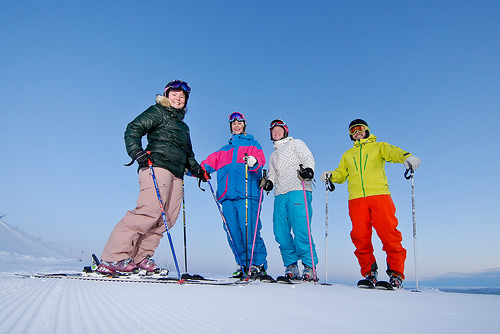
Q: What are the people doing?
A: Skiing.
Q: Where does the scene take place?
A: At a ski slope.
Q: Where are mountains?
A: In the far distance.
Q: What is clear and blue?
A: The sky.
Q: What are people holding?
A: Ski poles.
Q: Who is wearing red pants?
A: Person on far right.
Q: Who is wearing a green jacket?
A: Person on far left.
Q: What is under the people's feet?
A: Skis.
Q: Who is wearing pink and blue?
A: Second person from the left.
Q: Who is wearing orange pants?
A: The skier on the right.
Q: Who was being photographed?
A: A group of skiers.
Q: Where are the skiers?
A: On the snow.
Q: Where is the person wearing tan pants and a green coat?
A: On the left side.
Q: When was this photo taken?
A: During the daytime.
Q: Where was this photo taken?
A: During a ski trip.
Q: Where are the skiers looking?
A: Toward the camera.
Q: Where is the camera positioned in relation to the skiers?
A: Downhill.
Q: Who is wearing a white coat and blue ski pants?
A: The person who is second from the right.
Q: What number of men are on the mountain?
A: 4.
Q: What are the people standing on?
A: Snow.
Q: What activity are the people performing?
A: Skiing.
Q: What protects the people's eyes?
A: Goggles.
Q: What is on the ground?
A: Snow.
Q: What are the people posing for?
A: Picture.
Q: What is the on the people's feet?
A: Skis.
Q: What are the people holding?
A: Poles.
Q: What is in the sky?
A: Nothing.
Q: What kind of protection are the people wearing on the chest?
A: Jackets.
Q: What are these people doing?
A: Skiing.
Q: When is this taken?
A: During the day.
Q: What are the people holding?
A: Poles.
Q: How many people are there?
A: Four.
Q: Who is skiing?
A: The men and women.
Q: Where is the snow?
A: On the ground.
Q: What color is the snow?
A: White.